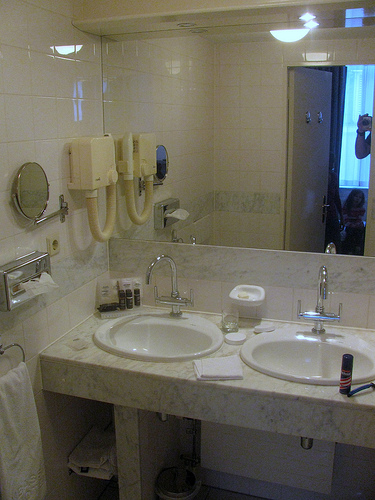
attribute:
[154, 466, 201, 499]
garbage can — silver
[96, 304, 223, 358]
sink — white 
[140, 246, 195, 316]
faucet — silver 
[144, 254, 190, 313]
faucet — large 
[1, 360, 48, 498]
towel — white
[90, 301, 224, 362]
sink — white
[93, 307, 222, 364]
sink — large, white, round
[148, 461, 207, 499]
trashcan — small 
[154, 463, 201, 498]
plastic bag —  plastic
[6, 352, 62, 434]
towel — hanging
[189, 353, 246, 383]
cloth rag — small, square, white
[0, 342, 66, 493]
towel — white 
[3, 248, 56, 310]
holder — silver, tissue paper holder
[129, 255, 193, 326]
faucet — chrome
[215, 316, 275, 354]
soap — small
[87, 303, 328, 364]
bathroom sink — white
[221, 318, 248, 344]
container — small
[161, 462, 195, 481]
can — garbage